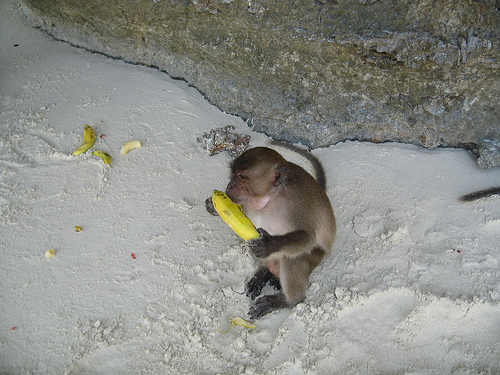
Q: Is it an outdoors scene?
A: Yes, it is outdoors.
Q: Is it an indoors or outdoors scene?
A: It is outdoors.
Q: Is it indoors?
A: No, it is outdoors.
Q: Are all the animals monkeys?
A: Yes, all the animals are monkeys.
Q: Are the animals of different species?
A: No, all the animals are monkeys.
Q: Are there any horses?
A: No, there are no horses.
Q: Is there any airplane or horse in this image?
A: No, there are no horses or airplanes.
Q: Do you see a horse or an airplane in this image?
A: No, there are no horses or airplanes.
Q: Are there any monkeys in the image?
A: Yes, there is a monkey.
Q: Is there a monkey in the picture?
A: Yes, there is a monkey.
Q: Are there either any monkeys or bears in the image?
A: Yes, there is a monkey.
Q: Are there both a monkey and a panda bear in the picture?
A: No, there is a monkey but no pandas.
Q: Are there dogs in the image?
A: No, there are no dogs.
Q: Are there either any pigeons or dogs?
A: No, there are no dogs or pigeons.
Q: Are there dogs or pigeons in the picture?
A: No, there are no dogs or pigeons.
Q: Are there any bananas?
A: Yes, there is a banana.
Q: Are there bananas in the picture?
A: Yes, there is a banana.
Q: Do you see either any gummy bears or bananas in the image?
A: Yes, there is a banana.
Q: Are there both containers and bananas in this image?
A: No, there is a banana but no containers.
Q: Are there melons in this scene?
A: No, there are no melons.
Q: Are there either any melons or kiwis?
A: No, there are no melons or kiwis.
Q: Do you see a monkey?
A: Yes, there is a monkey.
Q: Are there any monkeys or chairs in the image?
A: Yes, there is a monkey.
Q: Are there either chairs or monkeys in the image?
A: Yes, there is a monkey.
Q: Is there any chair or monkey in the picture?
A: Yes, there is a monkey.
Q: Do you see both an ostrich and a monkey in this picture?
A: No, there is a monkey but no ostriches.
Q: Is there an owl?
A: No, there are no owls.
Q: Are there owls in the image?
A: No, there are no owls.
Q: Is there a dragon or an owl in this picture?
A: No, there are no owls or dragons.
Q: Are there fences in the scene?
A: No, there are no fences.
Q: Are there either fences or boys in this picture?
A: No, there are no fences or boys.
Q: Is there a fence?
A: No, there are no fences.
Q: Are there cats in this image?
A: No, there are no cats.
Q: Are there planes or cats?
A: No, there are no cats or planes.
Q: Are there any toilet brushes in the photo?
A: No, there are no toilet brushes.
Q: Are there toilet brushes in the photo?
A: No, there are no toilet brushes.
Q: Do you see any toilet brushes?
A: No, there are no toilet brushes.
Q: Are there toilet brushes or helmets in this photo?
A: No, there are no toilet brushes or helmets.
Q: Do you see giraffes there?
A: No, there are no giraffes.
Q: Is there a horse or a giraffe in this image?
A: No, there are no giraffes or horses.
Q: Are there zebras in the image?
A: No, there are no zebras.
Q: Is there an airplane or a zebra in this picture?
A: No, there are no zebras or airplanes.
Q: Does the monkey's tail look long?
A: Yes, the tail is long.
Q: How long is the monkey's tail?
A: The tail is long.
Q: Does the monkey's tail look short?
A: No, the tail is long.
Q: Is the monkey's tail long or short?
A: The tail is long.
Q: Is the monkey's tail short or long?
A: The tail is long.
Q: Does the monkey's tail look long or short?
A: The tail is long.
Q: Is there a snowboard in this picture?
A: No, there are no snowboards.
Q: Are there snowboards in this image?
A: No, there are no snowboards.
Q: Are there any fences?
A: No, there are no fences.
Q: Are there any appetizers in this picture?
A: No, there are no appetizers.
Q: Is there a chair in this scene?
A: No, there are no chairs.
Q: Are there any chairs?
A: No, there are no chairs.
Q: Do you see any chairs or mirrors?
A: No, there are no chairs or mirrors.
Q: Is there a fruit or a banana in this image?
A: Yes, there is a banana.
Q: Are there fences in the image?
A: No, there are no fences.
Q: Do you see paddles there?
A: No, there are no paddles.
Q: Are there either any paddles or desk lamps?
A: No, there are no paddles or desk lamps.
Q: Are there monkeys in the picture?
A: Yes, there is a monkey.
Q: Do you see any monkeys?
A: Yes, there is a monkey.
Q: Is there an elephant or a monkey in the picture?
A: Yes, there is a monkey.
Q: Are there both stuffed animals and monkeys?
A: No, there is a monkey but no stuffed animals.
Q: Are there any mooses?
A: No, there are no mooses.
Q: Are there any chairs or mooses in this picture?
A: No, there are no mooses or chairs.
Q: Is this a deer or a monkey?
A: This is a monkey.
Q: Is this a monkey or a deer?
A: This is a monkey.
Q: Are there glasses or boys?
A: No, there are no boys or glasses.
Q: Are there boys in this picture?
A: No, there are no boys.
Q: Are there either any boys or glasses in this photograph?
A: No, there are no boys or glasses.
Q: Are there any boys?
A: No, there are no boys.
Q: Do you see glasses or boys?
A: No, there are no boys or glasses.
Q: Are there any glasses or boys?
A: No, there are no boys or glasses.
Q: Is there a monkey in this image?
A: Yes, there is a monkey.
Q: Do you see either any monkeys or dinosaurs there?
A: Yes, there is a monkey.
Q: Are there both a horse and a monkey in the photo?
A: No, there is a monkey but no horses.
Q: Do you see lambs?
A: No, there are no lambs.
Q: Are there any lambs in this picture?
A: No, there are no lambs.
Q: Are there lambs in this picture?
A: No, there are no lambs.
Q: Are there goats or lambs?
A: No, there are no lambs or goats.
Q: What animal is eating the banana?
A: The monkey is eating the banana.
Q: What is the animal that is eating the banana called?
A: The animal is a monkey.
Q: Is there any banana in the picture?
A: Yes, there is a banana.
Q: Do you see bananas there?
A: Yes, there is a banana.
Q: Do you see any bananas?
A: Yes, there is a banana.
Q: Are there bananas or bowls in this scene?
A: Yes, there is a banana.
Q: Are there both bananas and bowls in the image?
A: No, there is a banana but no bowls.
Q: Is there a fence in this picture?
A: No, there are no fences.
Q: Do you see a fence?
A: No, there are no fences.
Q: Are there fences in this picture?
A: No, there are no fences.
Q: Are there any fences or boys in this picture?
A: No, there are no fences or boys.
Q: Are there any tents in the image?
A: No, there are no tents.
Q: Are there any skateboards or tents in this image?
A: No, there are no tents or skateboards.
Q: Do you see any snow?
A: Yes, there is snow.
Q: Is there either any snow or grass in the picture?
A: Yes, there is snow.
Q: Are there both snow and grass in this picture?
A: No, there is snow but no grass.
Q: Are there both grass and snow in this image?
A: No, there is snow but no grass.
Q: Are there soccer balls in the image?
A: No, there are no soccer balls.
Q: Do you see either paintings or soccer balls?
A: No, there are no soccer balls or paintings.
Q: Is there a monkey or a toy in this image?
A: Yes, there is a monkey.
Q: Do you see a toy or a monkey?
A: Yes, there is a monkey.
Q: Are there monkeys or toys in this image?
A: Yes, there is a monkey.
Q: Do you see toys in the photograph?
A: No, there are no toys.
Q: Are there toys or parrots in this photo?
A: No, there are no toys or parrots.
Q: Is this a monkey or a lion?
A: This is a monkey.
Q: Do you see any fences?
A: No, there are no fences.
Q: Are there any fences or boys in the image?
A: No, there are no fences or boys.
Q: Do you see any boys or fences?
A: No, there are no fences or boys.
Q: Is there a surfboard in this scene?
A: No, there are no surfboards.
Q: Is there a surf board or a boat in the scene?
A: No, there are no surfboards or boats.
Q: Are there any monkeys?
A: Yes, there is a monkey.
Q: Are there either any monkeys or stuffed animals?
A: Yes, there is a monkey.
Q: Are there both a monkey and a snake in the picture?
A: No, there is a monkey but no snakes.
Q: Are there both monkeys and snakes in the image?
A: No, there is a monkey but no snakes.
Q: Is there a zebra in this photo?
A: No, there are no zebras.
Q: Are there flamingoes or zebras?
A: No, there are no zebras or flamingoes.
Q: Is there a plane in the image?
A: No, there are no airplanes.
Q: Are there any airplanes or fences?
A: No, there are no airplanes or fences.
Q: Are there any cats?
A: No, there are no cats.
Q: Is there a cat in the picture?
A: No, there are no cats.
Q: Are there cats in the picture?
A: No, there are no cats.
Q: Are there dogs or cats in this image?
A: No, there are no cats or dogs.